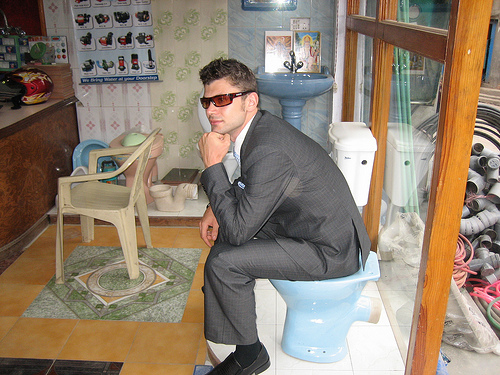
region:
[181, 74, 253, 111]
dark glasess on man's face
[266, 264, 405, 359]
light blue bottom of toliet with no seat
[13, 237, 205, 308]
green tiled design on floor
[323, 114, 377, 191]
white back of toliet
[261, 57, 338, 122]
light blue sink in rear of photo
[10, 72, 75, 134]
red helmet on counter top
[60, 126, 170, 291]
beige plastic lawn chair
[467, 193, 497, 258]
large amount of plumbing pipes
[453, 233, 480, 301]
orange extension cords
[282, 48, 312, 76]
silver bathroom water faucet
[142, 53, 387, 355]
man with the gray suit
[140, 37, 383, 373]
man sitting on the toilet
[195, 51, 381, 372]
Man in suit sitting on blue toilet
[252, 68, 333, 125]
Blue sink against the wall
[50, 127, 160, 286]
Tan plastic chair in front of the counter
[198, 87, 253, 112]
Sunglasses over man's eyes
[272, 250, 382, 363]
Part of a blue toilet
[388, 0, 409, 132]
Green shower curtain reflected in glass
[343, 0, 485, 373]
Large partition window with wooden trim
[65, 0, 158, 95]
Poster on the wall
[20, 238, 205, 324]
Tile inlay in floor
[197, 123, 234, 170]
Man's hand under his chin